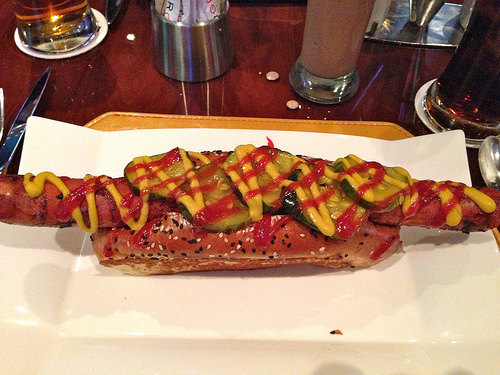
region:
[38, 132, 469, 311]
This is a hot dog.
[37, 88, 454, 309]
The hot dog has multiple toppings.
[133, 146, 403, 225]
These are pickels.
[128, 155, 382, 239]
There is ketchup on the pickles.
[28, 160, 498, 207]
There is mustard on the hot dog.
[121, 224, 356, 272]
The bun has seeds.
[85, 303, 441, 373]
The plate is white.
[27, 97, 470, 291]
the hot dog is long.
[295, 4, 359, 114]
this is a glass.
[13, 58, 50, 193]
This looks like a knife.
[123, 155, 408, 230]
Pickles on a hot dog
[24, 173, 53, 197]
Mustard on a hot dog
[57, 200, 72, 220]
Ketchup on a hot dog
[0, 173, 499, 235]
Hot dog on a bun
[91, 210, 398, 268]
Black and white seeds on a bun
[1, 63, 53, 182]
Knife on a table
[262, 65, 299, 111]
Two pink pills on a table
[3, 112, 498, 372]
White paper under a hot dog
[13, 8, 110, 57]
White coaster under a drink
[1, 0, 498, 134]
Brown table with several glasses on it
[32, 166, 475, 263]
hot dog on paper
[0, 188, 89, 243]
end of hot dog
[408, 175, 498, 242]
end of hot dog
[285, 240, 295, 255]
seed on the bun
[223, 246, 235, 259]
seed on the bun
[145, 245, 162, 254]
seed on the bun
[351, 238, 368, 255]
seed on the bun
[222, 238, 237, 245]
seed on the bun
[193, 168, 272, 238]
pickle on the dog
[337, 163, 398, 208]
pickle on the dog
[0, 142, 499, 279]
a sandwich with two hot dogs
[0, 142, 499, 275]
two hot dogs over a bun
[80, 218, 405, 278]
a bun under hot dogs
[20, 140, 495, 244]
mustard over hot dogs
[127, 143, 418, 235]
slices of pickles over hot dog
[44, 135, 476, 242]
ketchup on hot dogs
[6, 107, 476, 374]
hot dog over a white paper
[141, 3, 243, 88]
a silver container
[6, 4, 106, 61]
a glass of drink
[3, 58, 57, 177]
a knife over a table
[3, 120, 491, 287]
an elaborate hotdog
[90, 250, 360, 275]
crust of bread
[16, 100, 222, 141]
white paper on a ceramic plate underneath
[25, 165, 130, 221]
streaks of mustard and ketchup on a frank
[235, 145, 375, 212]
pickles covered with condiments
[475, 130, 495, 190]
head of a silver spoon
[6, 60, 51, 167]
silver knife at the dish's side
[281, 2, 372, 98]
chocolate drink in a glass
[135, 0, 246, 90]
bowl with packets of sugar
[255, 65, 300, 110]
drops of spilt chocolate